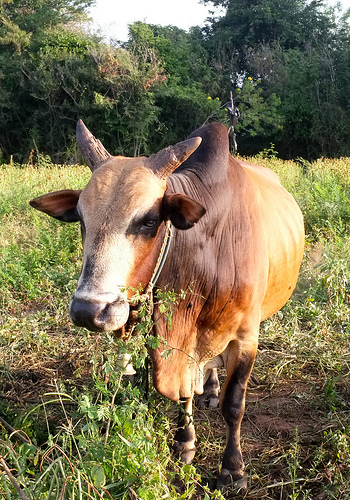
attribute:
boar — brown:
[52, 117, 345, 369]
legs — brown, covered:
[179, 383, 244, 500]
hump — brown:
[177, 127, 265, 176]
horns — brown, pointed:
[63, 122, 199, 178]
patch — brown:
[261, 387, 309, 449]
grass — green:
[302, 172, 339, 219]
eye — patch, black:
[136, 216, 161, 228]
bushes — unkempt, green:
[54, 394, 150, 470]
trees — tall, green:
[135, 25, 326, 123]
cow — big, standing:
[23, 123, 307, 469]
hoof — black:
[227, 468, 260, 497]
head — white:
[27, 142, 163, 311]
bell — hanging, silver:
[111, 348, 149, 386]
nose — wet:
[76, 293, 125, 336]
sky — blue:
[111, 8, 137, 26]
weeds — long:
[1, 164, 37, 204]